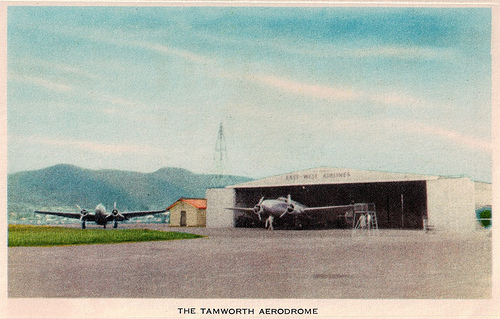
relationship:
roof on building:
[169, 191, 207, 211] [162, 195, 213, 230]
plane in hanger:
[220, 196, 379, 225] [206, 170, 491, 235]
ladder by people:
[352, 198, 387, 231] [356, 211, 380, 227]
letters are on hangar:
[281, 169, 357, 185] [200, 168, 491, 239]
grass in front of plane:
[3, 215, 203, 249] [35, 198, 188, 233]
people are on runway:
[356, 211, 380, 227] [169, 224, 499, 292]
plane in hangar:
[220, 196, 379, 225] [200, 168, 491, 239]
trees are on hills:
[48, 177, 104, 193] [11, 157, 264, 213]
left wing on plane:
[215, 195, 268, 218] [220, 196, 379, 225]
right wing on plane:
[294, 199, 359, 216] [220, 196, 379, 225]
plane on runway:
[35, 198, 188, 233] [4, 202, 499, 302]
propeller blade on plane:
[246, 194, 266, 225] [220, 196, 379, 225]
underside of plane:
[262, 208, 316, 228] [220, 196, 379, 225]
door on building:
[172, 206, 192, 230] [162, 195, 213, 230]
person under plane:
[261, 210, 278, 228] [220, 196, 379, 225]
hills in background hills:
[6, 157, 264, 217] [11, 157, 264, 213]